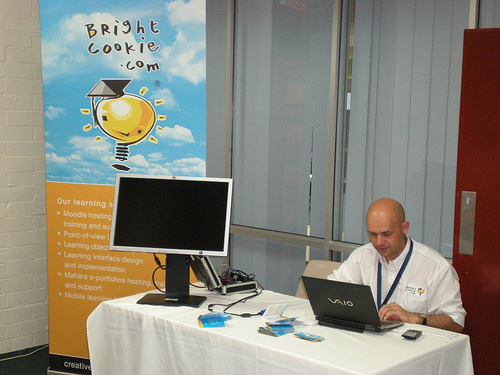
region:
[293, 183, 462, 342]
man working on laptop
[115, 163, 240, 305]
black and silver monitor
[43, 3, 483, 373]
man sitting at table for trade show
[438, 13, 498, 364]
red door behind man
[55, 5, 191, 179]
advertisement for brightcookie.com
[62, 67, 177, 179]
light bulb logo with black graduation cap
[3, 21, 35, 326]
wall made of white brick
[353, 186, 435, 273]
man with bald head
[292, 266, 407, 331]
black VAIO laptop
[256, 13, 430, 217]
long white blinds covering windows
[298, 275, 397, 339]
open gray Vaio laptop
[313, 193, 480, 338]
bald man using computer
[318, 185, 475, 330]
bald man wearing black watch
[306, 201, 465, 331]
bald man wearing white shirt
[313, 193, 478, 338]
bald man wearing blue ribbon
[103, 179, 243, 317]
large flat screen desktop computer on display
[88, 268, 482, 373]
table with white table cloth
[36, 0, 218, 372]
large blue and orange sign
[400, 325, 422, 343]
black cell phone on white table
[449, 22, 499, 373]
red door behind man with silver handle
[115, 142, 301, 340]
Monitor on table.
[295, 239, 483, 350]
Lap top on table.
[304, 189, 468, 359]
Man sitting at a table.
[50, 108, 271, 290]
Sign against the wall.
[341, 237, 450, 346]
Lanyard on man's neck.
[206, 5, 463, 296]
Windows on the wall.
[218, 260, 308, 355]
Cords on the table.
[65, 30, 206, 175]
Words on the sign.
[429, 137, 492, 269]
Red door on the wall.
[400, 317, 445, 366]
Phone on the table.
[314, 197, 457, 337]
balding man on a vaio laptop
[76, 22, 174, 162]
advertisement for bright cookie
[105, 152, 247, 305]
free standing computer monitor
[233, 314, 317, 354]
brochures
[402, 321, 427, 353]
mans cell phone on the table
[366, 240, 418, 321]
lanyard around a mans neck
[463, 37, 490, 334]
red door with silver push square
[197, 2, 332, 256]
large indoor windows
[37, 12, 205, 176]
advertisement with a light bulb and clouds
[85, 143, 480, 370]
man working at a table event for bright cookie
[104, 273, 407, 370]
White cloth on a table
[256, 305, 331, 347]
Blue paper on a table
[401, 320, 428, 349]
Black phone on a table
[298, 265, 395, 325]
Black laptop on a table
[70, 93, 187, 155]
Yellow light bulb on a sign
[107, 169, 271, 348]
Computer monitor on a table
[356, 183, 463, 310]
Man with a bald head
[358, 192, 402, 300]
Man with a blue lanyard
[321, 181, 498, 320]
Man in a white shirt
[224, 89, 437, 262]
Windows behind a man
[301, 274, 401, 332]
an open laptop computer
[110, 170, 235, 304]
a large computer monitor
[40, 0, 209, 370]
a business promotional banner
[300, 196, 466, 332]
a man using a computer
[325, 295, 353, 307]
a VAIO computer logo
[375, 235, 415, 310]
a blue neck lanyard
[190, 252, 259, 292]
a black and metal case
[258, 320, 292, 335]
a stack of business card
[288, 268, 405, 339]
black vaio laptop on table